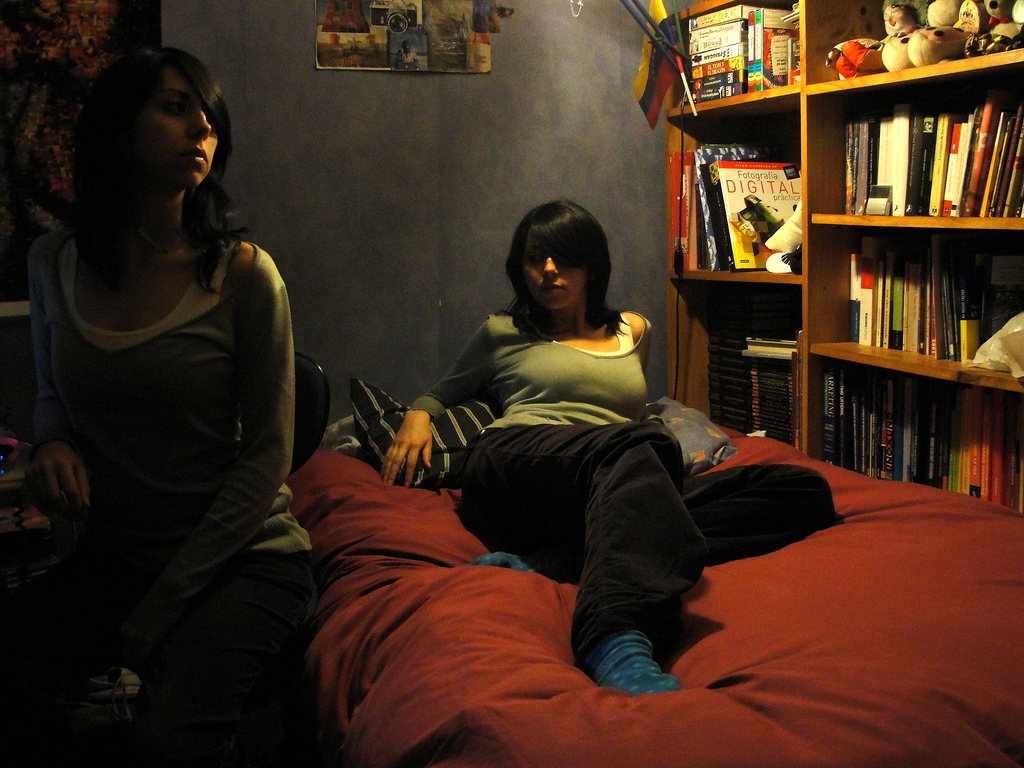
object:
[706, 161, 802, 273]
book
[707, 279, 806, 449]
book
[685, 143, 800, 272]
book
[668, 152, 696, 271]
book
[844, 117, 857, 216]
book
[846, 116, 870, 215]
book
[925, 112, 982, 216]
book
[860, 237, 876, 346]
book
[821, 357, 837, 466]
book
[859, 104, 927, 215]
book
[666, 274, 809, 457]
shelf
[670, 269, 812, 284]
shelf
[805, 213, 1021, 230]
shelf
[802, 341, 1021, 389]
shelf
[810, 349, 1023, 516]
shelf